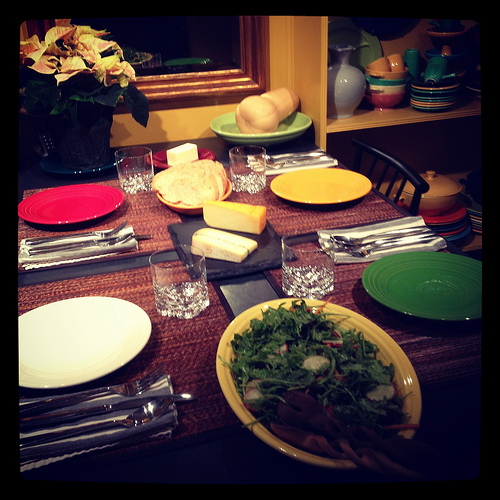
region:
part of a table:
[228, 333, 239, 342]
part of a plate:
[399, 307, 406, 319]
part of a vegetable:
[321, 335, 330, 344]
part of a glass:
[306, 270, 313, 287]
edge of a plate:
[110, 323, 112, 330]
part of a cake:
[225, 218, 239, 246]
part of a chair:
[406, 183, 414, 215]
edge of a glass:
[186, 287, 193, 295]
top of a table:
[213, 395, 235, 428]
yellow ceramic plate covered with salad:
[218, 292, 424, 467]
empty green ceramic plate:
[353, 249, 485, 321]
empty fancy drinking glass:
[146, 245, 211, 318]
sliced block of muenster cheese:
[202, 201, 267, 233]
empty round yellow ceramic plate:
[270, 164, 371, 206]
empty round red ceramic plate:
[15, 186, 127, 225]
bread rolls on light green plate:
[207, 79, 315, 148]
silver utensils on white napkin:
[21, 224, 141, 262]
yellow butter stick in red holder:
[146, 138, 216, 164]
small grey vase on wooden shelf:
[322, 39, 368, 129]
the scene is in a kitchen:
[31, 25, 451, 455]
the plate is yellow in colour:
[256, 160, 388, 214]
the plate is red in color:
[14, 166, 129, 242]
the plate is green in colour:
[371, 225, 488, 332]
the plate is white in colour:
[16, 293, 168, 404]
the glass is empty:
[142, 226, 221, 327]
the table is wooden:
[156, 338, 185, 368]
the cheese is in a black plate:
[172, 197, 285, 281]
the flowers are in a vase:
[13, 15, 160, 183]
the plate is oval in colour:
[181, 259, 426, 497]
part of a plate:
[420, 318, 437, 323]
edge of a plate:
[412, 295, 421, 303]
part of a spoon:
[158, 416, 168, 426]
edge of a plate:
[94, 345, 117, 381]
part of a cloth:
[201, 445, 217, 472]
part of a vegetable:
[273, 358, 293, 383]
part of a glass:
[190, 275, 201, 284]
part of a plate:
[113, 331, 117, 340]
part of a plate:
[425, 286, 431, 291]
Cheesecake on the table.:
[186, 201, 269, 261]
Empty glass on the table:
[146, 253, 228, 314]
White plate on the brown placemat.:
[35, 298, 167, 385]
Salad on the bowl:
[263, 330, 365, 412]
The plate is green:
[366, 258, 469, 331]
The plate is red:
[39, 172, 119, 224]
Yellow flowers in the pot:
[43, 37, 115, 159]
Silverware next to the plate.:
[40, 400, 160, 456]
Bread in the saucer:
[161, 160, 232, 214]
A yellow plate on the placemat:
[270, 164, 356, 213]